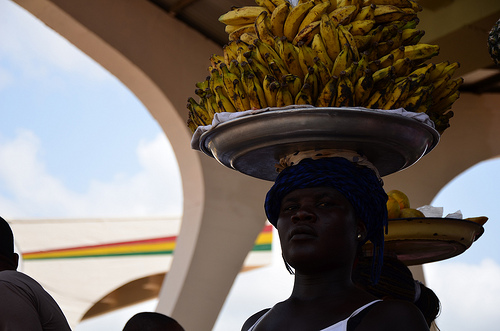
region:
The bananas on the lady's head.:
[173, 0, 459, 127]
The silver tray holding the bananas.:
[186, 105, 438, 175]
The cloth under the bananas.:
[182, 108, 446, 138]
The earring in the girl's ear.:
[356, 228, 365, 242]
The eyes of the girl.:
[282, 200, 338, 213]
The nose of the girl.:
[282, 207, 325, 222]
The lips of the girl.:
[280, 221, 321, 243]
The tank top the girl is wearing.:
[232, 293, 387, 330]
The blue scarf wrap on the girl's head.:
[254, 158, 394, 232]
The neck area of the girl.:
[286, 268, 350, 295]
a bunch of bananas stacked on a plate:
[183, 0, 464, 132]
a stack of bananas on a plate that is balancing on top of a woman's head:
[184, 0, 463, 130]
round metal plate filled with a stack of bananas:
[196, 107, 439, 181]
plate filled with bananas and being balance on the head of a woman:
[198, 108, 443, 180]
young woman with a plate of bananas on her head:
[240, 159, 433, 329]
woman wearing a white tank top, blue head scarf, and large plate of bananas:
[243, 158, 427, 330]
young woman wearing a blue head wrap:
[242, 160, 428, 330]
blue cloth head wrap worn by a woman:
[263, 155, 387, 287]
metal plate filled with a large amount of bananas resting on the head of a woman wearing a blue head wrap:
[198, 105, 440, 181]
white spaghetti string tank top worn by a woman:
[245, 297, 382, 329]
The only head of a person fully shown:
[254, 152, 391, 274]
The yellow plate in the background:
[375, 215, 491, 267]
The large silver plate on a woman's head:
[192, 107, 445, 185]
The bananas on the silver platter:
[182, 0, 459, 135]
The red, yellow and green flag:
[12, 218, 277, 260]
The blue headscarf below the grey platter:
[260, 155, 397, 224]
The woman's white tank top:
[242, 292, 384, 329]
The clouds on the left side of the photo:
[0, 0, 185, 217]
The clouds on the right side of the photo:
[424, 149, 499, 329]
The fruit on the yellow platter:
[382, 184, 432, 221]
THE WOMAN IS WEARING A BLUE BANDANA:
[252, 155, 397, 286]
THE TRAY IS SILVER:
[198, 100, 443, 182]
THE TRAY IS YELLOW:
[355, 208, 483, 264]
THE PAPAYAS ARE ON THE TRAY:
[380, 185, 430, 223]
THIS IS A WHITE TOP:
[228, 285, 414, 328]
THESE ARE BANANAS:
[181, 2, 466, 147]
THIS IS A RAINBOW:
[10, 218, 276, 259]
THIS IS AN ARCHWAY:
[2, 0, 209, 330]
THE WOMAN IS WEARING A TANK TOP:
[221, 280, 392, 327]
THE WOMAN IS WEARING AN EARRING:
[353, 228, 371, 253]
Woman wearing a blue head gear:
[225, 158, 432, 329]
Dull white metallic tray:
[189, 103, 443, 182]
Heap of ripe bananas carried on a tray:
[181, 2, 466, 181]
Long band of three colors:
[21, 219, 275, 259]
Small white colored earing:
[355, 231, 362, 239]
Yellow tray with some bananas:
[372, 188, 486, 267]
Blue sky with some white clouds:
[0, 106, 187, 221]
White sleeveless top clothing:
[231, 295, 428, 330]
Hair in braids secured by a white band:
[352, 249, 443, 328]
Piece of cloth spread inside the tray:
[185, 101, 437, 149]